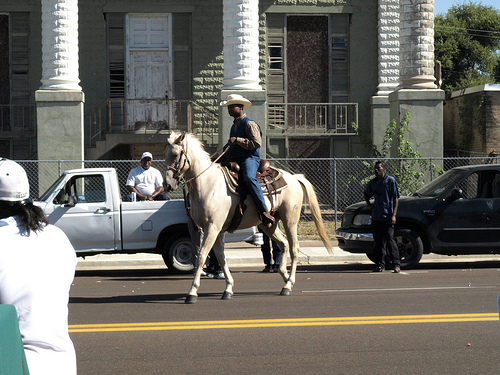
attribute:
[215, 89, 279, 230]
man — cowboy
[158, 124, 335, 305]
horse — white, walking, nice, beautiful, healthy, tan, gray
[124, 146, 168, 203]
man — sitting down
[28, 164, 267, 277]
truck — white, pick up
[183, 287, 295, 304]
hooves — black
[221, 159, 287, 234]
saddle — brown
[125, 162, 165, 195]
shirt — white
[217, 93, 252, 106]
cowboy hat — white, tan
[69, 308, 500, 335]
lines — yellow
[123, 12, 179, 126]
door — white, dirty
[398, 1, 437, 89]
pillar — stone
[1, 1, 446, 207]
building — old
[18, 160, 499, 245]
fence — chain link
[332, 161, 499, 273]
suv — black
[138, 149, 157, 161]
hat — white